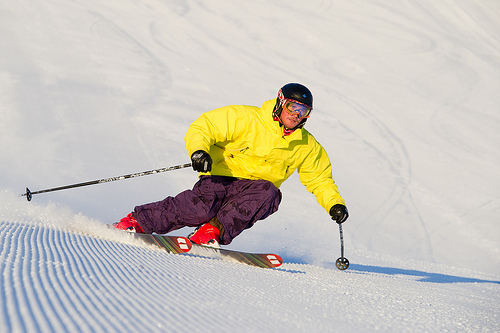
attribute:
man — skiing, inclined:
[17, 76, 358, 268]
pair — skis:
[11, 158, 354, 275]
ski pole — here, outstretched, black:
[21, 160, 192, 206]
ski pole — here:
[335, 221, 351, 270]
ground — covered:
[5, 7, 500, 327]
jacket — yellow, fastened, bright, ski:
[166, 100, 354, 212]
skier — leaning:
[22, 78, 359, 272]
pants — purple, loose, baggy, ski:
[123, 173, 279, 232]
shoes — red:
[110, 216, 218, 246]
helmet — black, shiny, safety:
[271, 81, 318, 127]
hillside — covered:
[3, 1, 499, 282]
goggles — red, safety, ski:
[278, 92, 316, 117]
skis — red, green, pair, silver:
[15, 156, 352, 270]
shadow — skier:
[273, 252, 500, 289]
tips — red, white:
[172, 234, 286, 271]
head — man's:
[271, 82, 314, 134]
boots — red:
[112, 214, 231, 246]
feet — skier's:
[113, 212, 224, 237]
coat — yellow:
[185, 99, 358, 212]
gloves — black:
[192, 148, 347, 224]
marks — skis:
[2, 211, 500, 331]